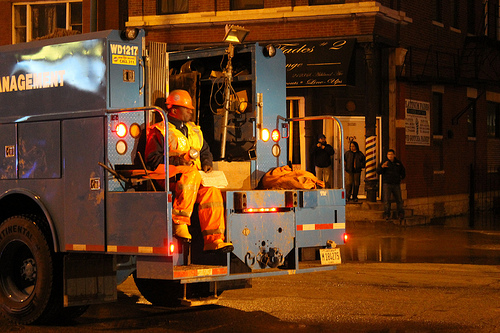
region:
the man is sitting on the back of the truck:
[156, 85, 236, 253]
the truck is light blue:
[261, 69, 279, 96]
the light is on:
[269, 122, 284, 145]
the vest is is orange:
[171, 133, 185, 148]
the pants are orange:
[183, 178, 195, 198]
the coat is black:
[388, 166, 396, 176]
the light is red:
[111, 118, 128, 140]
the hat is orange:
[169, 91, 187, 108]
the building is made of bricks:
[308, 21, 335, 36]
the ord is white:
[11, 68, 72, 92]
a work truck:
[1, 20, 364, 327]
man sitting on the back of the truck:
[131, 82, 244, 264]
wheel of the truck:
[0, 192, 98, 329]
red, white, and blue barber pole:
[356, 113, 380, 207]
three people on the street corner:
[305, 129, 412, 225]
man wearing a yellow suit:
[133, 76, 241, 258]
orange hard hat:
[160, 84, 197, 113]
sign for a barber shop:
[241, 33, 361, 95]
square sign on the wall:
[398, 92, 437, 149]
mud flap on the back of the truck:
[57, 241, 124, 313]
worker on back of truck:
[183, 199, 240, 259]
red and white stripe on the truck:
[113, 245, 154, 257]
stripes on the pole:
[355, 129, 385, 179]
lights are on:
[246, 127, 275, 142]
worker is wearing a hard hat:
[159, 73, 206, 102]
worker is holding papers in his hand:
[191, 163, 224, 203]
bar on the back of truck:
[128, 103, 177, 134]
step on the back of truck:
[183, 289, 229, 311]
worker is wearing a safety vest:
[153, 113, 171, 146]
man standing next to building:
[379, 154, 409, 189]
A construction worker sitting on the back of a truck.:
[142, 78, 237, 257]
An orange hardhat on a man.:
[162, 81, 197, 128]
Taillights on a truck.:
[113, 120, 141, 156]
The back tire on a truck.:
[2, 209, 69, 326]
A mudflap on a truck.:
[57, 247, 127, 313]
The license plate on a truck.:
[316, 243, 346, 268]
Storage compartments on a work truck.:
[0, 109, 115, 248]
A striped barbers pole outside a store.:
[359, 128, 379, 181]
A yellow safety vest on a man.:
[149, 118, 207, 170]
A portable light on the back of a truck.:
[215, 21, 249, 160]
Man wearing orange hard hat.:
[169, 84, 216, 145]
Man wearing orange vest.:
[151, 115, 242, 190]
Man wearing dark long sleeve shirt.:
[145, 118, 250, 171]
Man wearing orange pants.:
[175, 180, 260, 245]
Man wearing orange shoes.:
[172, 222, 248, 251]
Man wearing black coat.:
[371, 160, 413, 198]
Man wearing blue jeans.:
[374, 176, 414, 216]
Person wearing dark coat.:
[341, 141, 364, 164]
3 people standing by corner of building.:
[295, 97, 441, 220]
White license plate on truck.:
[322, 235, 370, 290]